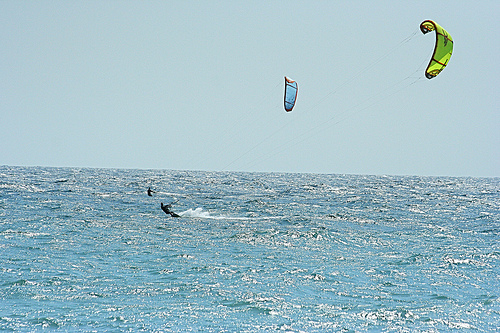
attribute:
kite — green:
[408, 12, 460, 85]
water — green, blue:
[0, 164, 499, 331]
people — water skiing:
[137, 186, 178, 218]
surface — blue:
[385, 187, 482, 281]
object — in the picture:
[273, 71, 300, 127]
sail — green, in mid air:
[409, 19, 460, 81]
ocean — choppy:
[89, 222, 377, 303]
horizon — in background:
[59, 75, 249, 164]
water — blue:
[50, 235, 487, 325]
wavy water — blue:
[177, 185, 357, 226]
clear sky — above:
[2, 10, 495, 162]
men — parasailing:
[148, 185, 177, 218]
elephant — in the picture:
[414, 13, 463, 83]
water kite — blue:
[281, 73, 301, 114]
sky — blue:
[4, 3, 474, 151]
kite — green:
[411, 10, 456, 88]